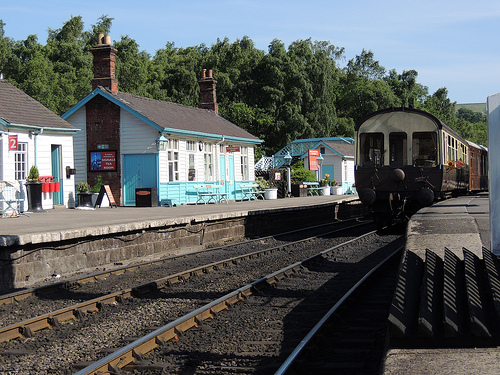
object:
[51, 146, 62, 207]
door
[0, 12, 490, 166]
trees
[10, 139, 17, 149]
number2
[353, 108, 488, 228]
train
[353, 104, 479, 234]
carry on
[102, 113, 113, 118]
brick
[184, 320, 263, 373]
gravel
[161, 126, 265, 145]
edge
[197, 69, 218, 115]
chimneys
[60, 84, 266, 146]
roof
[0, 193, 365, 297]
platform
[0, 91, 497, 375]
station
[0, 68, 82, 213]
building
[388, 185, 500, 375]
platform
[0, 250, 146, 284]
wall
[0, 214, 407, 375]
tracks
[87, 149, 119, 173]
sign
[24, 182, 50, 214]
pot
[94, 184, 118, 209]
sign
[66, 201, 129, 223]
ground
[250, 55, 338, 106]
leaves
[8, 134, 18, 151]
sign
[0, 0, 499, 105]
sky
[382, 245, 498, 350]
ridges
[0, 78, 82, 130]
roof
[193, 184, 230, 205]
chair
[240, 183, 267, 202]
chair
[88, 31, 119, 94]
chimney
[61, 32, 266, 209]
building